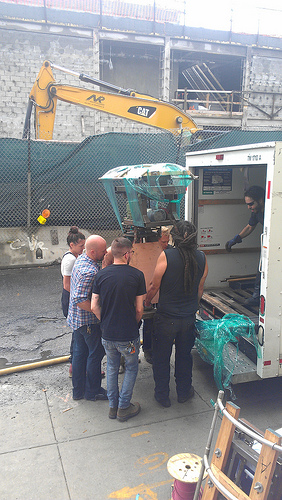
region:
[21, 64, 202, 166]
arm of heavy equipment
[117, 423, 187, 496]
yellow stains on the concrete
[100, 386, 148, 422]
brown work boots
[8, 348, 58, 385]
a yellow hose on the ground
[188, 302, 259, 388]
green plastic wrap on the truck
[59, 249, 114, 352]
a blue plaid shirt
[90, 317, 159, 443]
blue jeans on a guy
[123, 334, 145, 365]
keys clipped to a belt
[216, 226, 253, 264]
a man wearing gloves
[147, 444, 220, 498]
a red spool on the ground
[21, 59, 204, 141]
Yellow caterpillar behind fence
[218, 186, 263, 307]
Man in truck wearing glove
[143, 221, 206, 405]
Man has long dreadlocks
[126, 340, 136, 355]
Keys dangling off pocket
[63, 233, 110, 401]
Man wearing plaid shirt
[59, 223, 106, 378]
Woman wearing jean overalls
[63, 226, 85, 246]
Hair up in bun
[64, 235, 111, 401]
Man is bald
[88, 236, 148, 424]
Man wearing eye glasses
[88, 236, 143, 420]
Man carrying large equipment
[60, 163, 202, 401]
Workers lifting heavy machine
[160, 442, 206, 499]
White spool with pink wire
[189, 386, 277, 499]
Wooden pallet with metal bars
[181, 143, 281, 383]
Workers putting machine in white truck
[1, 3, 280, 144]
Yellow machine arm with Cat on it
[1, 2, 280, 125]
Gray brick building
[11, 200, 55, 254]
Flashing yellow,black and orange light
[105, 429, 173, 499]
yellow writing on cement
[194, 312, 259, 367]
Blue green plastic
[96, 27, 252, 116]
Two openings in building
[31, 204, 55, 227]
Reflector light in metal fence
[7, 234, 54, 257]
White writing on cement wall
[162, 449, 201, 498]
Spool of red wire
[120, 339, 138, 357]
Keys hanging out of back pocket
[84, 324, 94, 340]
Keys hanging on hips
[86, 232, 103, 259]
Man has a bald head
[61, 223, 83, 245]
Woman hair is in bun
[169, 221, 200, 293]
Man has long dreadlocks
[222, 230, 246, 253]
Man is wearing blue gloves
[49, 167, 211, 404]
People lifting heavy equipment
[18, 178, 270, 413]
a group of people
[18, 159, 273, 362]
a group of people carrying something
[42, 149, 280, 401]
a group of men carrying machinary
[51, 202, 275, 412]
a group of men holding somethign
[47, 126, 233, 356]
group of men holding machinary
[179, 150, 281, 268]
a man in the back of a truck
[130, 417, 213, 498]
a large spool of wire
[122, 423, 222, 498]
a spool of wire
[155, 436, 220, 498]
a wooden spool with wire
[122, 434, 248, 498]
a spool of colored wire